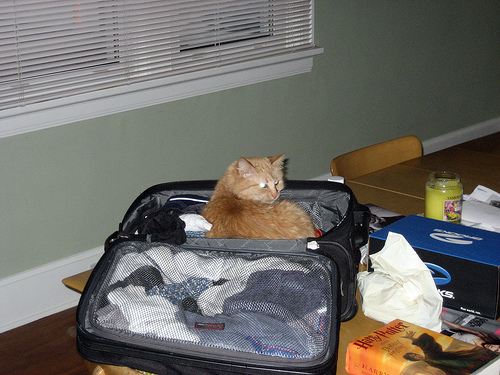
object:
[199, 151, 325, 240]
cat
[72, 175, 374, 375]
case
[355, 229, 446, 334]
cloth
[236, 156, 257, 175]
ear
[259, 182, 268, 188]
eye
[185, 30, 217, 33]
blinds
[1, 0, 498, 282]
wall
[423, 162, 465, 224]
candle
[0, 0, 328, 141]
windowsill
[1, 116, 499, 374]
baseboard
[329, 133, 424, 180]
chair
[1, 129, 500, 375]
table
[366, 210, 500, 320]
shoe box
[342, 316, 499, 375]
book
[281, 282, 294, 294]
clothes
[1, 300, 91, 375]
floor